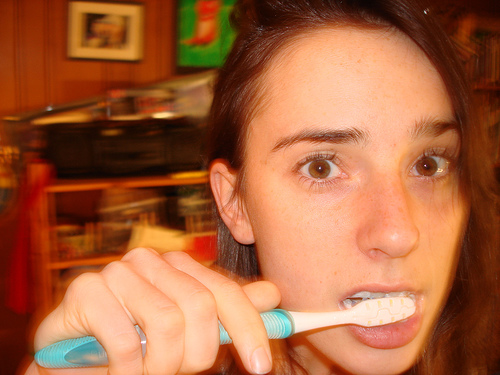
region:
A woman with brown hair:
[204, 17, 486, 369]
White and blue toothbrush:
[46, 304, 428, 362]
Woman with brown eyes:
[293, 122, 450, 202]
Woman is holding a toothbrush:
[53, 39, 446, 355]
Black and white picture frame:
[61, 12, 147, 69]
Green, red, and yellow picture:
[166, 15, 237, 75]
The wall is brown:
[13, 10, 163, 126]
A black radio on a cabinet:
[33, 105, 227, 187]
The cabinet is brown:
[22, 162, 231, 322]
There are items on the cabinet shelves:
[37, 175, 228, 300]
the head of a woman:
[195, 0, 480, 372]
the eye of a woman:
[286, 145, 359, 188]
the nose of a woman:
[352, 152, 423, 264]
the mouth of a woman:
[333, 272, 432, 357]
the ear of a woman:
[204, 157, 261, 247]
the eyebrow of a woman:
[265, 123, 374, 153]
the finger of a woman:
[161, 243, 278, 373]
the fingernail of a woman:
[248, 342, 272, 374]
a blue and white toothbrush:
[32, 294, 423, 373]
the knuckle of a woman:
[68, 266, 105, 302]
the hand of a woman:
[29, 240, 295, 372]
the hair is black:
[224, 60, 241, 132]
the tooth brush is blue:
[35, 300, 404, 330]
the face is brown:
[277, 58, 459, 353]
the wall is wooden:
[14, 70, 111, 97]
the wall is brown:
[9, 72, 85, 99]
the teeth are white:
[352, 293, 417, 318]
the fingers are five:
[60, 249, 273, 360]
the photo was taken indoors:
[3, 59, 498, 368]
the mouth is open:
[343, 275, 435, 334]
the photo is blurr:
[14, 118, 168, 220]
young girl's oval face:
[209, 2, 493, 374]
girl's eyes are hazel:
[293, 150, 455, 185]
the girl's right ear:
[208, 159, 256, 244]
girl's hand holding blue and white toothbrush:
[33, 246, 416, 373]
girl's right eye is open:
[209, 3, 494, 373]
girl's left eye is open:
[208, 3, 479, 373]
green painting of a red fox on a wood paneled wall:
[0, 0, 239, 120]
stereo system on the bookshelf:
[23, 117, 240, 372]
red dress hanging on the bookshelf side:
[1, 154, 236, 320]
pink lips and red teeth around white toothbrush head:
[285, 280, 426, 349]